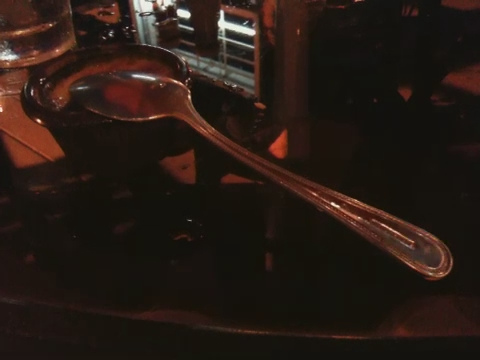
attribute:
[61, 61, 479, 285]
spoon — silver, steel, metal, dirty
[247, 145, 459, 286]
handle — silver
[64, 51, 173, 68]
bowl — small, black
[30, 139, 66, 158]
table — brown, wooden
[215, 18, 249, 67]
racks — metal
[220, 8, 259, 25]
frame — metal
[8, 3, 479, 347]
place — dark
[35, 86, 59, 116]
dish — black, brown, small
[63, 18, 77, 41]
glass — clear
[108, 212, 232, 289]
countertop — black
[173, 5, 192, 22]
light — white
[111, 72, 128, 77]
spots — black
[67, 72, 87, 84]
cream — brown